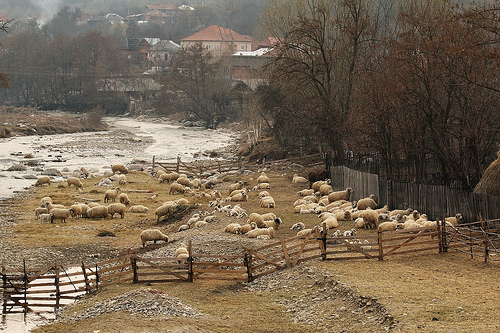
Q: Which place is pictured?
A: It is a pen.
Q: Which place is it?
A: It is a pen.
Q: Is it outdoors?
A: Yes, it is outdoors.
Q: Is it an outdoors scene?
A: Yes, it is outdoors.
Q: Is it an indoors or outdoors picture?
A: It is outdoors.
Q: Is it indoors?
A: No, it is outdoors.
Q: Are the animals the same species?
A: No, there are both sheep and horses.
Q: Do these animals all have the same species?
A: No, there are both sheep and horses.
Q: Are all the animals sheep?
A: No, there are both sheep and horses.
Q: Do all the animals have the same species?
A: No, there are both sheep and horses.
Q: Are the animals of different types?
A: Yes, they are sheep and horses.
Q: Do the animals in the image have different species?
A: Yes, they are sheep and horses.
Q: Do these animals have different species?
A: Yes, they are sheep and horses.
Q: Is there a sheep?
A: Yes, there is a sheep.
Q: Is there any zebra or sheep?
A: Yes, there is a sheep.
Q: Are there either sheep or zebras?
A: Yes, there is a sheep.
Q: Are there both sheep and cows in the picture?
A: No, there is a sheep but no cows.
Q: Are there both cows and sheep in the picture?
A: No, there is a sheep but no cows.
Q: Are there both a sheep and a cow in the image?
A: No, there is a sheep but no cows.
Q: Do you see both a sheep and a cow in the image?
A: No, there is a sheep but no cows.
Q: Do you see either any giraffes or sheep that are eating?
A: Yes, the sheep is eating.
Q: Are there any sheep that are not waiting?
A: Yes, there is a sheep that is eating.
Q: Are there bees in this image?
A: No, there are no bees.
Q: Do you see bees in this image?
A: No, there are no bees.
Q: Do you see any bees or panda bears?
A: No, there are no bees or panda bears.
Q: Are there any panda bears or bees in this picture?
A: No, there are no bees or panda bears.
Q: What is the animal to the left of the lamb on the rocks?
A: The animal is a sheep.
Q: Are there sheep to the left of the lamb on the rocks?
A: Yes, there is a sheep to the left of the lamb.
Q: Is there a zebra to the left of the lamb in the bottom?
A: No, there is a sheep to the left of the lamb.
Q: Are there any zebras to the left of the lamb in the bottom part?
A: No, there is a sheep to the left of the lamb.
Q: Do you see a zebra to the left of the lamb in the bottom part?
A: No, there is a sheep to the left of the lamb.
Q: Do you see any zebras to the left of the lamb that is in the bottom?
A: No, there is a sheep to the left of the lamb.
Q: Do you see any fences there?
A: Yes, there is a fence.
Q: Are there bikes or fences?
A: Yes, there is a fence.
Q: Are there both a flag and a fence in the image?
A: No, there is a fence but no flags.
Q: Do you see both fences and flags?
A: No, there is a fence but no flags.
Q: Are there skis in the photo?
A: No, there are no skis.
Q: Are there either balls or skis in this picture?
A: No, there are no skis or balls.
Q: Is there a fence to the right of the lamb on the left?
A: Yes, there is a fence to the right of the lamb.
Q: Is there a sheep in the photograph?
A: Yes, there is a sheep.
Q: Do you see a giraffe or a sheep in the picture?
A: Yes, there is a sheep.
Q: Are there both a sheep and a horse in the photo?
A: Yes, there are both a sheep and a horse.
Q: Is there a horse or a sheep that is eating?
A: Yes, the sheep is eating.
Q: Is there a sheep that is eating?
A: Yes, there is a sheep that is eating.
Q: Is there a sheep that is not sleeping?
A: Yes, there is a sheep that is eating.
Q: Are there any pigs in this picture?
A: No, there are no pigs.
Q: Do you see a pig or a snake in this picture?
A: No, there are no pigs or snakes.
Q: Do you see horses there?
A: Yes, there is a horse.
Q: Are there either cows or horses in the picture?
A: Yes, there is a horse.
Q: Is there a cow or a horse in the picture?
A: Yes, there is a horse.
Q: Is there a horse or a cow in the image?
A: Yes, there is a horse.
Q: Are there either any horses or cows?
A: Yes, there is a horse.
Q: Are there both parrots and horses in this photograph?
A: No, there is a horse but no parrots.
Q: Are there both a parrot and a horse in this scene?
A: No, there is a horse but no parrots.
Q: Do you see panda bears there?
A: No, there are no panda bears.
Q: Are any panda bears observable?
A: No, there are no panda bears.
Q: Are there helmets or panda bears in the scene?
A: No, there are no panda bears or helmets.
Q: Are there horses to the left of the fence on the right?
A: Yes, there is a horse to the left of the fence.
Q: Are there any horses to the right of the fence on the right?
A: No, the horse is to the left of the fence.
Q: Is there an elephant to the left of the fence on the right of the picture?
A: No, there is a horse to the left of the fence.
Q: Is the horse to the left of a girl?
A: No, the horse is to the left of a fence.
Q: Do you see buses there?
A: No, there are no buses.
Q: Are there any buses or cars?
A: No, there are no buses or cars.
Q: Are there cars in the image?
A: No, there are no cars.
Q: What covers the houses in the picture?
A: The trees cover the houses.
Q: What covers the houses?
A: The trees cover the houses.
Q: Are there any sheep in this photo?
A: Yes, there is a sheep.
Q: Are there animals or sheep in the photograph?
A: Yes, there is a sheep.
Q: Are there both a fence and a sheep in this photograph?
A: Yes, there are both a sheep and a fence.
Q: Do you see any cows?
A: No, there are no cows.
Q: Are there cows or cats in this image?
A: No, there are no cows or cats.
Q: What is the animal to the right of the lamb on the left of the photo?
A: The animal is a sheep.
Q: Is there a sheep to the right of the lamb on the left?
A: Yes, there is a sheep to the right of the lamb.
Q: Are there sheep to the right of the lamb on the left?
A: Yes, there is a sheep to the right of the lamb.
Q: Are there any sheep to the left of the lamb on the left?
A: No, the sheep is to the right of the lamb.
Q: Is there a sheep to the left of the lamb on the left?
A: No, the sheep is to the right of the lamb.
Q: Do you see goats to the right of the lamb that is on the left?
A: No, there is a sheep to the right of the lamb.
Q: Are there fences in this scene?
A: Yes, there is a fence.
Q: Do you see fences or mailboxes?
A: Yes, there is a fence.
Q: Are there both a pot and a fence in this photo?
A: No, there is a fence but no pots.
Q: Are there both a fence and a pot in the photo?
A: No, there is a fence but no pots.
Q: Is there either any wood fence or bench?
A: Yes, there is a wood fence.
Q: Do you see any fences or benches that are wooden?
A: Yes, the fence is wooden.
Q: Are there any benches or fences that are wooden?
A: Yes, the fence is wooden.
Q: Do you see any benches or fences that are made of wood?
A: Yes, the fence is made of wood.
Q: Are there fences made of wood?
A: Yes, there is a fence that is made of wood.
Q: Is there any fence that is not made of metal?
A: Yes, there is a fence that is made of wood.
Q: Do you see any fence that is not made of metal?
A: Yes, there is a fence that is made of wood.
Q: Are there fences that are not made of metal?
A: Yes, there is a fence that is made of wood.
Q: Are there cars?
A: No, there are no cars.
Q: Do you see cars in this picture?
A: No, there are no cars.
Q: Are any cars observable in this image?
A: No, there are no cars.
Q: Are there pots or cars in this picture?
A: No, there are no cars or pots.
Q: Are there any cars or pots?
A: No, there are no cars or pots.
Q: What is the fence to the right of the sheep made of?
A: The fence is made of wood.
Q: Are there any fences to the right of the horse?
A: Yes, there is a fence to the right of the horse.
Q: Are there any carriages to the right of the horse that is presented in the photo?
A: No, there is a fence to the right of the horse.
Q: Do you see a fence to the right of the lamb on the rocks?
A: Yes, there is a fence to the right of the lamb.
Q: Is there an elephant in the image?
A: No, there are no elephants.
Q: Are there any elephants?
A: No, there are no elephants.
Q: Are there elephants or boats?
A: No, there are no elephants or boats.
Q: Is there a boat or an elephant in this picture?
A: No, there are no elephants or boats.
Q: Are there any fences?
A: Yes, there is a fence.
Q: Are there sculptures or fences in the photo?
A: Yes, there is a fence.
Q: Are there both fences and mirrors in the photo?
A: No, there is a fence but no mirrors.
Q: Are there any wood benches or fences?
A: Yes, there is a wood fence.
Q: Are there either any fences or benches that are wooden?
A: Yes, the fence is wooden.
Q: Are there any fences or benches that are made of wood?
A: Yes, the fence is made of wood.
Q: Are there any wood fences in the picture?
A: Yes, there is a wood fence.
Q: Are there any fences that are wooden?
A: Yes, there is a fence that is wooden.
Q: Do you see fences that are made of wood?
A: Yes, there is a fence that is made of wood.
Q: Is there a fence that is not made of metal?
A: Yes, there is a fence that is made of wood.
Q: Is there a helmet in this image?
A: No, there are no helmets.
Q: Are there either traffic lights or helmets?
A: No, there are no helmets or traffic lights.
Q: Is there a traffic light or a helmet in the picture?
A: No, there are no helmets or traffic lights.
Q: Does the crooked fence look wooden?
A: Yes, the fence is wooden.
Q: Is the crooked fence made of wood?
A: Yes, the fence is made of wood.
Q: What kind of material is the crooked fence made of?
A: The fence is made of wood.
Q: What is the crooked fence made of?
A: The fence is made of wood.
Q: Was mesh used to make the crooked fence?
A: No, the fence is made of wood.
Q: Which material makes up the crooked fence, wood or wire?
A: The fence is made of wood.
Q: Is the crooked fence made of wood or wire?
A: The fence is made of wood.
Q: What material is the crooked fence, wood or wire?
A: The fence is made of wood.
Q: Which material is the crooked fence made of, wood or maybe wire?
A: The fence is made of wood.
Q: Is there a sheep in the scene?
A: Yes, there is a sheep.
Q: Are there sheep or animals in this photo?
A: Yes, there is a sheep.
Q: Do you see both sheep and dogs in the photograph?
A: No, there is a sheep but no dogs.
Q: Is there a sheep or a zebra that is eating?
A: Yes, the sheep is eating.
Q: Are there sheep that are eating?
A: Yes, there is a sheep that is eating.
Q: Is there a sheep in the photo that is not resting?
A: Yes, there is a sheep that is eating.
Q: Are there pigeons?
A: No, there are no pigeons.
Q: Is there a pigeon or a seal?
A: No, there are no pigeons or seals.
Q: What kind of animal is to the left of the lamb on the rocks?
A: The animal is a sheep.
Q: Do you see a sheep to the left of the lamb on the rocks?
A: Yes, there is a sheep to the left of the lamb.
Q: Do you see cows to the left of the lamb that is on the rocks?
A: No, there is a sheep to the left of the lamb.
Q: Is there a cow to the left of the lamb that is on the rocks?
A: No, there is a sheep to the left of the lamb.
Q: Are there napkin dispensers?
A: No, there are no napkin dispensers.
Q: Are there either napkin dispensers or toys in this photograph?
A: No, there are no napkin dispensers or toys.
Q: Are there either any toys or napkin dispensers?
A: No, there are no napkin dispensers or toys.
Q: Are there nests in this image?
A: No, there are no nests.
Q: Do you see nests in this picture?
A: No, there are no nests.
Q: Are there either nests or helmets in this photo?
A: No, there are no nests or helmets.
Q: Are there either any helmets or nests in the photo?
A: No, there are no nests or helmets.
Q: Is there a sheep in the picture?
A: Yes, there is a sheep.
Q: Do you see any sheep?
A: Yes, there is a sheep.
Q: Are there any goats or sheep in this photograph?
A: Yes, there is a sheep.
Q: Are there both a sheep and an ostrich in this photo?
A: No, there is a sheep but no ostriches.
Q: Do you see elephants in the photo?
A: No, there are no elephants.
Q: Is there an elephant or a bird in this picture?
A: No, there are no elephants or birds.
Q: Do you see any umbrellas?
A: No, there are no umbrellas.